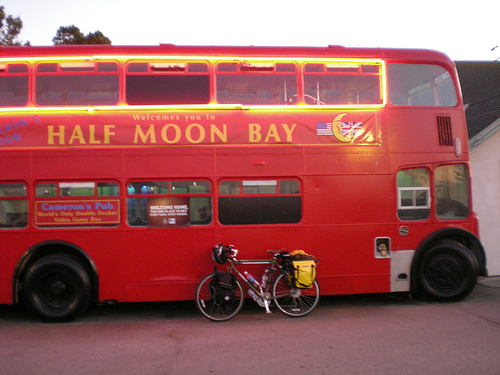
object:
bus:
[1, 42, 491, 322]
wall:
[472, 163, 500, 233]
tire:
[20, 252, 95, 322]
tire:
[415, 240, 480, 302]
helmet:
[210, 243, 239, 264]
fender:
[413, 225, 491, 279]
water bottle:
[243, 271, 259, 289]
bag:
[282, 250, 321, 289]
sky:
[0, 2, 496, 57]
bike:
[196, 243, 321, 322]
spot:
[376, 240, 388, 257]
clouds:
[0, 0, 498, 62]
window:
[126, 180, 212, 225]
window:
[218, 175, 301, 224]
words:
[42, 121, 298, 144]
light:
[0, 55, 389, 114]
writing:
[43, 122, 296, 145]